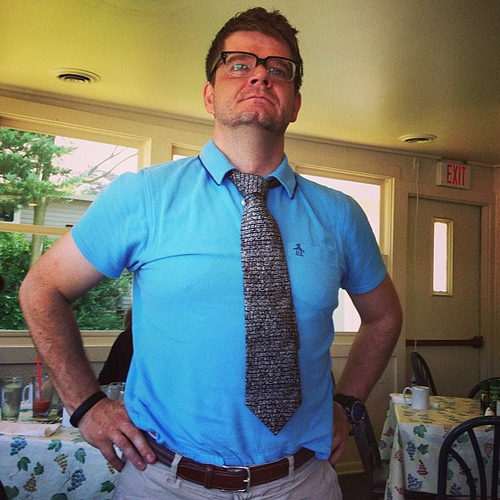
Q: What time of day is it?
A: Daytime.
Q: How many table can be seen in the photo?
A: 2.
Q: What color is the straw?
A: Red.